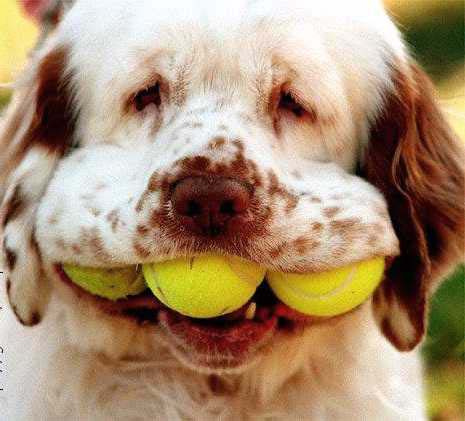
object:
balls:
[265, 253, 387, 317]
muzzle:
[58, 253, 381, 322]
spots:
[78, 215, 122, 257]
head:
[1, 1, 464, 394]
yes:
[167, 103, 269, 176]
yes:
[248, 168, 333, 264]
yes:
[74, 167, 172, 250]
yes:
[130, 129, 300, 272]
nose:
[169, 176, 250, 236]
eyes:
[278, 86, 311, 124]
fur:
[238, 358, 307, 401]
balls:
[59, 264, 147, 298]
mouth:
[47, 209, 391, 373]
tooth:
[244, 302, 257, 321]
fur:
[24, 329, 151, 418]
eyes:
[123, 79, 161, 116]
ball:
[141, 251, 266, 318]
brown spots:
[265, 206, 360, 259]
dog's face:
[41, 2, 374, 257]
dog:
[0, 0, 464, 420]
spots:
[189, 141, 246, 171]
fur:
[320, 10, 370, 53]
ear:
[0, 26, 76, 327]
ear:
[359, 56, 463, 352]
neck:
[24, 299, 373, 418]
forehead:
[111, 5, 325, 90]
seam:
[272, 269, 370, 299]